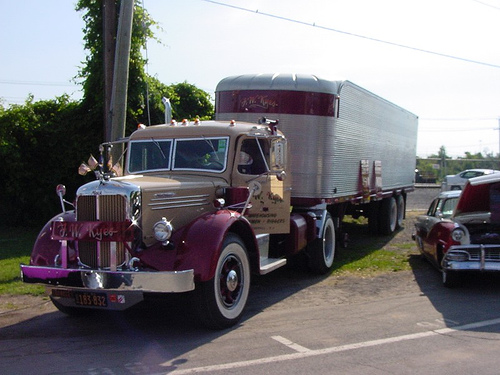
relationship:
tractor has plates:
[17, 95, 339, 333] [71, 289, 110, 309]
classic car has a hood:
[412, 170, 500, 290] [450, 168, 499, 222]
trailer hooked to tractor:
[213, 71, 421, 277] [17, 95, 339, 333]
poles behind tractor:
[99, 0, 137, 180] [17, 95, 339, 333]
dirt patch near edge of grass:
[0, 264, 445, 342] [1, 225, 418, 300]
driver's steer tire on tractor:
[192, 228, 256, 332] [17, 95, 339, 333]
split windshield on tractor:
[125, 134, 232, 176] [17, 95, 339, 333]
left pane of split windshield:
[169, 136, 231, 176] [125, 134, 232, 176]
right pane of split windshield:
[125, 137, 176, 175] [125, 134, 232, 176]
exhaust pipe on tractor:
[160, 96, 174, 126] [17, 95, 339, 333]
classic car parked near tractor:
[412, 170, 500, 290] [17, 95, 339, 333]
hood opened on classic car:
[450, 168, 499, 222] [412, 170, 500, 290]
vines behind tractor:
[1, 2, 217, 236] [17, 95, 339, 333]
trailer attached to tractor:
[213, 71, 421, 277] [17, 95, 339, 333]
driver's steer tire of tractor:
[192, 228, 256, 332] [17, 95, 339, 333]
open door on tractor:
[228, 131, 293, 236] [17, 95, 339, 333]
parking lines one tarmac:
[146, 315, 499, 375] [1, 290, 500, 375]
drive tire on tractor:
[284, 209, 339, 277] [17, 95, 339, 333]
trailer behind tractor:
[213, 71, 421, 277] [17, 95, 339, 333]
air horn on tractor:
[255, 114, 282, 136] [17, 95, 339, 333]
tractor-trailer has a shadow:
[19, 68, 421, 332] [1, 219, 405, 374]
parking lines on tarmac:
[146, 315, 499, 375] [1, 290, 500, 375]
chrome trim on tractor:
[147, 193, 213, 212] [17, 95, 339, 333]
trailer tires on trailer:
[366, 191, 407, 236] [213, 71, 421, 277]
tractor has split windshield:
[17, 95, 339, 333] [125, 134, 232, 176]